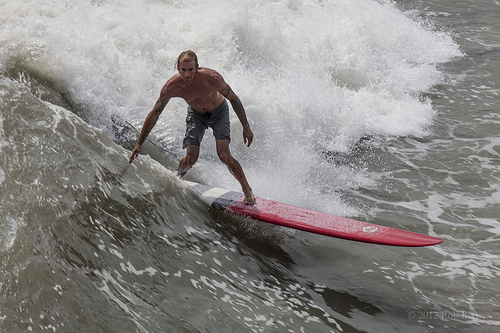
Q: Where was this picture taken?
A: The ocean.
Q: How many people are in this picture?
A: One.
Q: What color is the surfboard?
A: Red.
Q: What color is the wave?
A: White.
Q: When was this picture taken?
A: During the day.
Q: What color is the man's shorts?
A: Black.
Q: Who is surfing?
A: A man.